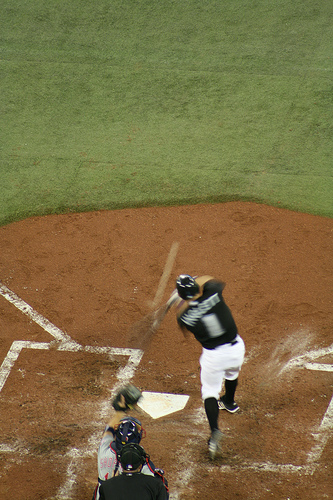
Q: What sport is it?
A: Baseball.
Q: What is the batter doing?
A: Swinging.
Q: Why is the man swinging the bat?
A: To hit the ball.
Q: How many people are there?
A: Three.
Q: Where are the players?
A: A baseball field.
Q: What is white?
A: Home plate.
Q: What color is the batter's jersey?
A: Black.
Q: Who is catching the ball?
A: The catcher.